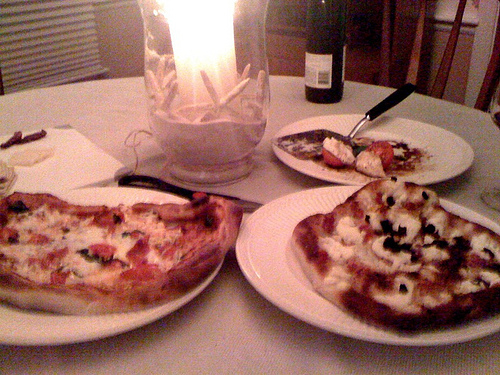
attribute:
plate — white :
[7, 122, 148, 197]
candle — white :
[163, 0, 247, 113]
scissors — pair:
[112, 166, 258, 218]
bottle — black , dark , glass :
[302, 0, 350, 105]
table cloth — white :
[25, 76, 180, 167]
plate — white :
[265, 111, 476, 189]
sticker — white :
[300, 48, 337, 93]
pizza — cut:
[9, 172, 244, 335]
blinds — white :
[13, 9, 122, 96]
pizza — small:
[287, 177, 499, 337]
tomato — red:
[330, 131, 390, 189]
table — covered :
[4, 65, 497, 370]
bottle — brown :
[295, 2, 359, 107]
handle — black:
[362, 80, 425, 124]